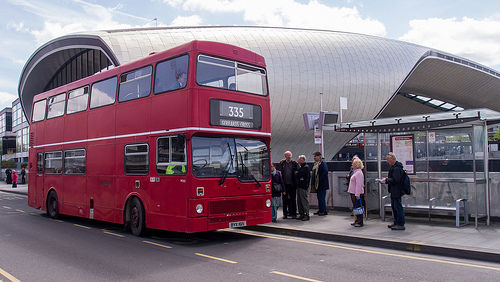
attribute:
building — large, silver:
[17, 24, 498, 164]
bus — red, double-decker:
[0, 26, 300, 258]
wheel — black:
[124, 192, 146, 237]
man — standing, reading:
[354, 108, 428, 248]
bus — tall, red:
[14, 37, 289, 252]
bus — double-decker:
[28, 38, 272, 237]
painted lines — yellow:
[269, 265, 326, 280]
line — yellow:
[1, 267, 20, 280]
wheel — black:
[127, 197, 151, 237]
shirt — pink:
[347, 169, 364, 196]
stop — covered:
[315, 111, 499, 246]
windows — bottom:
[29, 137, 185, 181]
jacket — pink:
[344, 169, 373, 201]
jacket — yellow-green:
[162, 160, 190, 180]